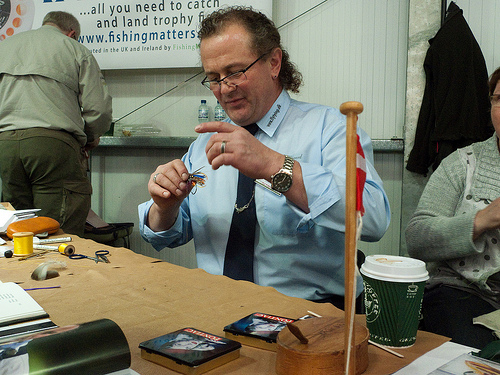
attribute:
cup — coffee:
[349, 223, 415, 360]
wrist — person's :
[264, 149, 301, 199]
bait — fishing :
[174, 160, 214, 187]